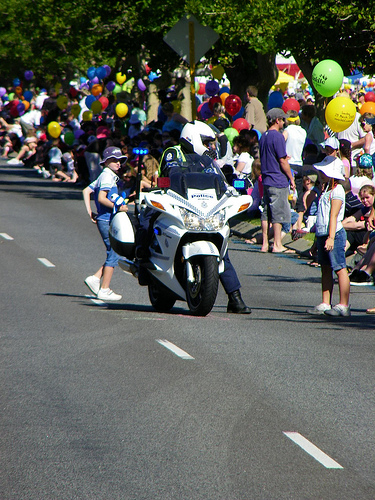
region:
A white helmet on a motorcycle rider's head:
[178, 117, 218, 156]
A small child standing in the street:
[304, 153, 353, 318]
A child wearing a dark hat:
[81, 145, 131, 300]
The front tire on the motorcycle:
[179, 253, 219, 318]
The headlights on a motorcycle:
[174, 203, 231, 234]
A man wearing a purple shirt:
[255, 107, 299, 257]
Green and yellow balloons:
[311, 55, 358, 134]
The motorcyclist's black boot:
[225, 286, 255, 316]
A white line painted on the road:
[282, 428, 344, 473]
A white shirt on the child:
[313, 182, 348, 235]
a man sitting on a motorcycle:
[139, 108, 248, 332]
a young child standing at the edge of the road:
[296, 149, 352, 325]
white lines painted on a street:
[158, 322, 359, 491]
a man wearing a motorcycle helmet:
[175, 116, 221, 166]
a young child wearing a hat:
[314, 158, 345, 188]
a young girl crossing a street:
[65, 135, 133, 318]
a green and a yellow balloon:
[306, 38, 361, 147]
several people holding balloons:
[17, 68, 134, 164]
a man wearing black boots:
[225, 278, 255, 323]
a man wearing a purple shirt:
[255, 122, 305, 184]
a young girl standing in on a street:
[301, 154, 348, 322]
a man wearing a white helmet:
[171, 115, 231, 165]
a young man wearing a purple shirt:
[255, 111, 293, 196]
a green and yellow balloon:
[306, 45, 362, 155]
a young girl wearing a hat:
[98, 143, 124, 177]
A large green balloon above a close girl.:
[310, 58, 341, 96]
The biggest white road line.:
[281, 430, 343, 468]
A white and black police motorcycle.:
[109, 172, 253, 312]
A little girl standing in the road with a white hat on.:
[306, 156, 352, 317]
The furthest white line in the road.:
[1, 231, 12, 241]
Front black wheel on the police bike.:
[182, 244, 220, 316]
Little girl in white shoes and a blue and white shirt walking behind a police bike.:
[82, 145, 128, 298]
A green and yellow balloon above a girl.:
[313, 57, 356, 132]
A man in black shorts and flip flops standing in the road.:
[257, 107, 298, 252]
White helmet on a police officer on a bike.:
[181, 119, 216, 157]